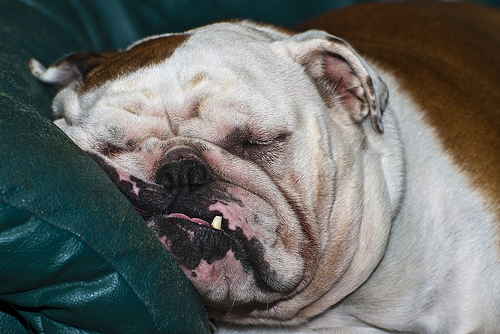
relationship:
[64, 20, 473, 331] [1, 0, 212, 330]
dog sleeping on pillow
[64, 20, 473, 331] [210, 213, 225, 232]
dog with tooth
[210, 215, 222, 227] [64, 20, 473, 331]
tooth sticking out of dog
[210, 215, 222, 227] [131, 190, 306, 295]
tooth sticking out of mouth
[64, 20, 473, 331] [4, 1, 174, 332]
dog sleeping on cushion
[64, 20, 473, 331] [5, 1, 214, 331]
dog sleeping on couch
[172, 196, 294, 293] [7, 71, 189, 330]
lip pulled up against cushion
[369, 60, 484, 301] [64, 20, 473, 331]
fur on dog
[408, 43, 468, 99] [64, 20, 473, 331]
fur on dog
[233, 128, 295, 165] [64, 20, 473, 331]
eye of dog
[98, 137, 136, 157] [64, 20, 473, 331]
eye of dog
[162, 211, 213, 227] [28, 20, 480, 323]
tongue of dog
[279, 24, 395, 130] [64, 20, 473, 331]
ear of dog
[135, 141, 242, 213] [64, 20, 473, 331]
nose of dog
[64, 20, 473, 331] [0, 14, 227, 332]
dog sleeping on cushion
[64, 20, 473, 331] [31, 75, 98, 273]
dog on pillow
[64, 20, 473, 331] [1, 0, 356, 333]
dog sleeping on pillow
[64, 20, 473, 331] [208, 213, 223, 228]
dog broken tooth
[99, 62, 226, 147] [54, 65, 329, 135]
furrow on forehead